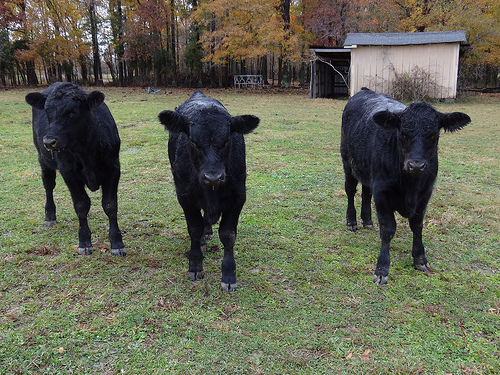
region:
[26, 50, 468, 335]
three black cows in a row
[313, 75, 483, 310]
a small black cow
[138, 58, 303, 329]
a small black cow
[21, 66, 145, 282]
a small black cow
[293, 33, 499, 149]
a wooden shed with an eaves drop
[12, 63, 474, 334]
three cows standing together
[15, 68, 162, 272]
couw with drool coming off of mouth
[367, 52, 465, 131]
dead foilage against shed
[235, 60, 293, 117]
a metal fence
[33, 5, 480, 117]
trees lining property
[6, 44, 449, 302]
Cows standing in a grassy field